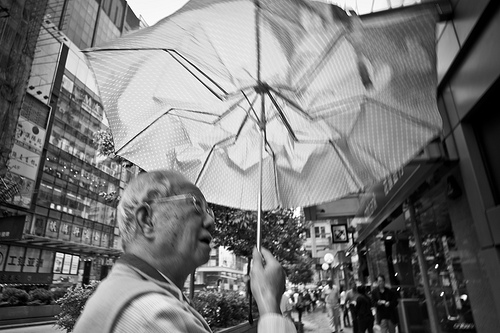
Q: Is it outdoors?
A: Yes, it is outdoors.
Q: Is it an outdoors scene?
A: Yes, it is outdoors.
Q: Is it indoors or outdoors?
A: It is outdoors.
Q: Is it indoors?
A: No, it is outdoors.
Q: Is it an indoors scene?
A: No, it is outdoors.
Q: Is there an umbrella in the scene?
A: Yes, there is an umbrella.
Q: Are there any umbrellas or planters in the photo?
A: Yes, there is an umbrella.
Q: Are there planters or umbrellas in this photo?
A: Yes, there is an umbrella.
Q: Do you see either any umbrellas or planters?
A: Yes, there is an umbrella.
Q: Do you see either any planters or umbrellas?
A: Yes, there is an umbrella.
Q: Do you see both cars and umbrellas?
A: No, there is an umbrella but no cars.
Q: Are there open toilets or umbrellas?
A: Yes, there is an open umbrella.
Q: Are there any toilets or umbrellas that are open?
A: Yes, the umbrella is open.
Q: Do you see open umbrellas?
A: Yes, there is an open umbrella.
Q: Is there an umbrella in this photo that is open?
A: Yes, there is an umbrella that is open.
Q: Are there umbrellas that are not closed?
A: Yes, there is a open umbrella.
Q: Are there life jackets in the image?
A: No, there are no life jackets.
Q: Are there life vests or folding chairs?
A: No, there are no life vests or folding chairs.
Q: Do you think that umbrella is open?
A: Yes, the umbrella is open.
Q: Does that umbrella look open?
A: Yes, the umbrella is open.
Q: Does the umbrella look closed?
A: No, the umbrella is open.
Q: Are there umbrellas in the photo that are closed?
A: No, there is an umbrella but it is open.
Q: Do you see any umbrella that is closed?
A: No, there is an umbrella but it is open.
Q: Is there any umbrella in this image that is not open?
A: No, there is an umbrella but it is open.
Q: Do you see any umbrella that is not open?
A: No, there is an umbrella but it is open.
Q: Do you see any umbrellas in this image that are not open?
A: No, there is an umbrella but it is open.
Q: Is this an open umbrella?
A: Yes, this is an open umbrella.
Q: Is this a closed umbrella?
A: No, this is an open umbrella.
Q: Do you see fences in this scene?
A: No, there are no fences.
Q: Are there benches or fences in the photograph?
A: No, there are no fences or benches.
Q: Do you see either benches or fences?
A: No, there are no fences or benches.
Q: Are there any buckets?
A: No, there are no buckets.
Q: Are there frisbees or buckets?
A: No, there are no buckets or frisbees.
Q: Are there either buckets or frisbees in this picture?
A: No, there are no buckets or frisbees.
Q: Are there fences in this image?
A: No, there are no fences.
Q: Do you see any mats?
A: No, there are no mats.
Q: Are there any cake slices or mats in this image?
A: No, there are no mats or cake slices.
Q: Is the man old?
A: Yes, the man is old.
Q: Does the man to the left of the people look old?
A: Yes, the man is old.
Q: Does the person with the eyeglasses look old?
A: Yes, the man is old.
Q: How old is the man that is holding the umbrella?
A: The man is old.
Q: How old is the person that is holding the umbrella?
A: The man is old.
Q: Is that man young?
A: No, the man is old.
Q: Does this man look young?
A: No, the man is old.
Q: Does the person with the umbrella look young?
A: No, the man is old.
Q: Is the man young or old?
A: The man is old.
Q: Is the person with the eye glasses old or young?
A: The man is old.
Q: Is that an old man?
A: Yes, that is an old man.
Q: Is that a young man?
A: No, that is an old man.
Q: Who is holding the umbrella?
A: The man is holding the umbrella.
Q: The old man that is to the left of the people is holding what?
A: The man is holding the umbrella.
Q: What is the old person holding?
A: The man is holding the umbrella.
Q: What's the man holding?
A: The man is holding the umbrella.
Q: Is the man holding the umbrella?
A: Yes, the man is holding the umbrella.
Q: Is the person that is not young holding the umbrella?
A: Yes, the man is holding the umbrella.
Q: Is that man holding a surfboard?
A: No, the man is holding the umbrella.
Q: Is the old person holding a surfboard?
A: No, the man is holding the umbrella.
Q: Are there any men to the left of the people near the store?
A: Yes, there is a man to the left of the people.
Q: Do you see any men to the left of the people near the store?
A: Yes, there is a man to the left of the people.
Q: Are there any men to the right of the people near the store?
A: No, the man is to the left of the people.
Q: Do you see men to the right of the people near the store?
A: No, the man is to the left of the people.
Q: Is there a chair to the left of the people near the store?
A: No, there is a man to the left of the people.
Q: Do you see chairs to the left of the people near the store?
A: No, there is a man to the left of the people.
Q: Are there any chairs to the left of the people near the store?
A: No, there is a man to the left of the people.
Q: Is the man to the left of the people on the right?
A: Yes, the man is to the left of the people.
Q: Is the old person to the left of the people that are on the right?
A: Yes, the man is to the left of the people.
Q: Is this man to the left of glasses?
A: No, the man is to the left of the people.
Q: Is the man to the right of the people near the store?
A: No, the man is to the left of the people.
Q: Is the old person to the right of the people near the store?
A: No, the man is to the left of the people.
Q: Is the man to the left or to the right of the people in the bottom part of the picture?
A: The man is to the left of the people.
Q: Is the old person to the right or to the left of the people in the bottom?
A: The man is to the left of the people.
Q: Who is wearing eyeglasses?
A: The man is wearing eyeglasses.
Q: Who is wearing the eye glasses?
A: The man is wearing eyeglasses.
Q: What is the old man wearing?
A: The man is wearing eyeglasses.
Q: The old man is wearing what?
A: The man is wearing eyeglasses.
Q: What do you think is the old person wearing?
A: The man is wearing eyeglasses.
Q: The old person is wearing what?
A: The man is wearing eyeglasses.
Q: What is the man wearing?
A: The man is wearing eyeglasses.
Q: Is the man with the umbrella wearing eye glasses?
A: Yes, the man is wearing eye glasses.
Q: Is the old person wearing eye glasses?
A: Yes, the man is wearing eye glasses.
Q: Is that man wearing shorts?
A: No, the man is wearing eye glasses.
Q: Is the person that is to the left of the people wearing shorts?
A: No, the man is wearing eye glasses.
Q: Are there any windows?
A: Yes, there are windows.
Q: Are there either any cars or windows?
A: Yes, there are windows.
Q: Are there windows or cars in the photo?
A: Yes, there are windows.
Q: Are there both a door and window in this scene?
A: No, there are windows but no doors.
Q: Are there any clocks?
A: No, there are no clocks.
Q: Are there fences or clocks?
A: No, there are no clocks or fences.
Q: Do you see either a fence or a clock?
A: No, there are no clocks or fences.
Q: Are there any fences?
A: No, there are no fences.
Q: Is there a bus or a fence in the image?
A: No, there are no fences or buses.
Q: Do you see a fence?
A: No, there are no fences.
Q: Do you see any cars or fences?
A: No, there are no fences or cars.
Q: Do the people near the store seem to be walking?
A: Yes, the people are walking.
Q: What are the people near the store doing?
A: The people are walking.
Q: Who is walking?
A: The people are walking.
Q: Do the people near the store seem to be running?
A: No, the people are walking.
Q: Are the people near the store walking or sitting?
A: The people are walking.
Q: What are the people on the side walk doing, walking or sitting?
A: The people are walking.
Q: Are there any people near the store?
A: Yes, there are people near the store.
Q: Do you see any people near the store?
A: Yes, there are people near the store.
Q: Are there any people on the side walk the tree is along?
A: Yes, there are people on the sidewalk.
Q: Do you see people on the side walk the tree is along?
A: Yes, there are people on the sidewalk.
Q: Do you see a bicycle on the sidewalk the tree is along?
A: No, there are people on the sidewalk.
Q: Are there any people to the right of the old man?
A: Yes, there are people to the right of the man.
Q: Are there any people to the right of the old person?
A: Yes, there are people to the right of the man.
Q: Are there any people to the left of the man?
A: No, the people are to the right of the man.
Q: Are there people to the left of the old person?
A: No, the people are to the right of the man.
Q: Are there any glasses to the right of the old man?
A: No, there are people to the right of the man.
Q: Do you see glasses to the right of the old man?
A: No, there are people to the right of the man.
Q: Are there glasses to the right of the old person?
A: No, there are people to the right of the man.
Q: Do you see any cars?
A: No, there are no cars.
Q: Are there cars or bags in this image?
A: No, there are no cars or bags.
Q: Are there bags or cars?
A: No, there are no cars or bags.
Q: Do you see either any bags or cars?
A: No, there are no cars or bags.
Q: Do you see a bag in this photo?
A: No, there are no bags.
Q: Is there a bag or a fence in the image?
A: No, there are no bags or fences.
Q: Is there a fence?
A: No, there are no fences.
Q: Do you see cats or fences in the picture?
A: No, there are no fences or cats.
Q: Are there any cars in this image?
A: No, there are no cars.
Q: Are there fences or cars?
A: No, there are no cars or fences.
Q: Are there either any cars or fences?
A: No, there are no cars or fences.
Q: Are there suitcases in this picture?
A: No, there are no suitcases.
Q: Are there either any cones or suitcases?
A: No, there are no suitcases or cones.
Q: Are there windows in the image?
A: Yes, there is a window.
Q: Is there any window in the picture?
A: Yes, there is a window.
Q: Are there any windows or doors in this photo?
A: Yes, there is a window.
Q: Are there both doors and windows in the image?
A: No, there is a window but no doors.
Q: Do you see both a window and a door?
A: No, there is a window but no doors.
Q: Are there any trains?
A: No, there are no trains.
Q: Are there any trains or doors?
A: No, there are no trains or doors.